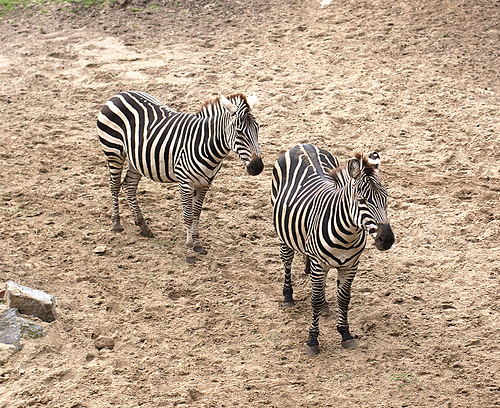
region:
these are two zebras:
[85, 77, 399, 338]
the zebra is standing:
[267, 130, 397, 334]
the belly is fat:
[270, 192, 315, 238]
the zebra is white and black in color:
[291, 192, 308, 224]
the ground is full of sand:
[138, 277, 233, 392]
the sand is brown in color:
[146, 292, 265, 379]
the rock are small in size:
[0, 274, 52, 324]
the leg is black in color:
[304, 333, 321, 348]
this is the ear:
[348, 157, 356, 172]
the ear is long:
[217, 88, 235, 111]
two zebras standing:
[97, 92, 392, 357]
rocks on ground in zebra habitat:
[2, 279, 53, 344]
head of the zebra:
[346, 147, 394, 250]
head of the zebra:
[215, 89, 262, 174]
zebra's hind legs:
[107, 155, 151, 235]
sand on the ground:
[1, 366, 498, 405]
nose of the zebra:
[372, 221, 392, 249]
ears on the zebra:
[346, 149, 381, 178]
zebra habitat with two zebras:
[2, 1, 499, 406]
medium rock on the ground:
[0, 278, 56, 324]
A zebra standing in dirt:
[273, 132, 395, 351]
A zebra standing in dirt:
[98, 80, 262, 260]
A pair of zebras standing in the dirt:
[96, 80, 394, 355]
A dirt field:
[1, 7, 493, 404]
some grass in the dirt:
[386, 367, 422, 385]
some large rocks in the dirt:
[0, 267, 62, 352]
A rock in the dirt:
[92, 333, 117, 347]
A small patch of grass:
[0, 0, 188, 23]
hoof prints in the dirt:
[8, 0, 498, 405]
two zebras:
[98, 56, 397, 352]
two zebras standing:
[90, 68, 425, 358]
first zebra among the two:
[267, 136, 408, 363]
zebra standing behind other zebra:
[76, 73, 264, 269]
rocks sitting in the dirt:
[2, 270, 64, 349]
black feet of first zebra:
[278, 286, 354, 353]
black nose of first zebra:
[372, 223, 399, 260]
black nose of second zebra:
[246, 155, 263, 176]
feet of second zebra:
[107, 208, 212, 267]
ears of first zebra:
[335, 149, 385, 184]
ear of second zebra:
[212, 89, 238, 119]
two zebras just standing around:
[69, 73, 426, 370]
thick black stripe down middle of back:
[298, 138, 333, 196]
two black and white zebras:
[80, 76, 413, 352]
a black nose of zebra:
[373, 221, 398, 255]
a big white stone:
[5, 274, 67, 336]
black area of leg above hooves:
[279, 282, 360, 359]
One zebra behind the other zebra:
[83, 74, 269, 286]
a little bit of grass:
[4, 1, 104, 28]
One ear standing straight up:
[333, 152, 383, 184]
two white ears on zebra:
[213, 91, 270, 124]